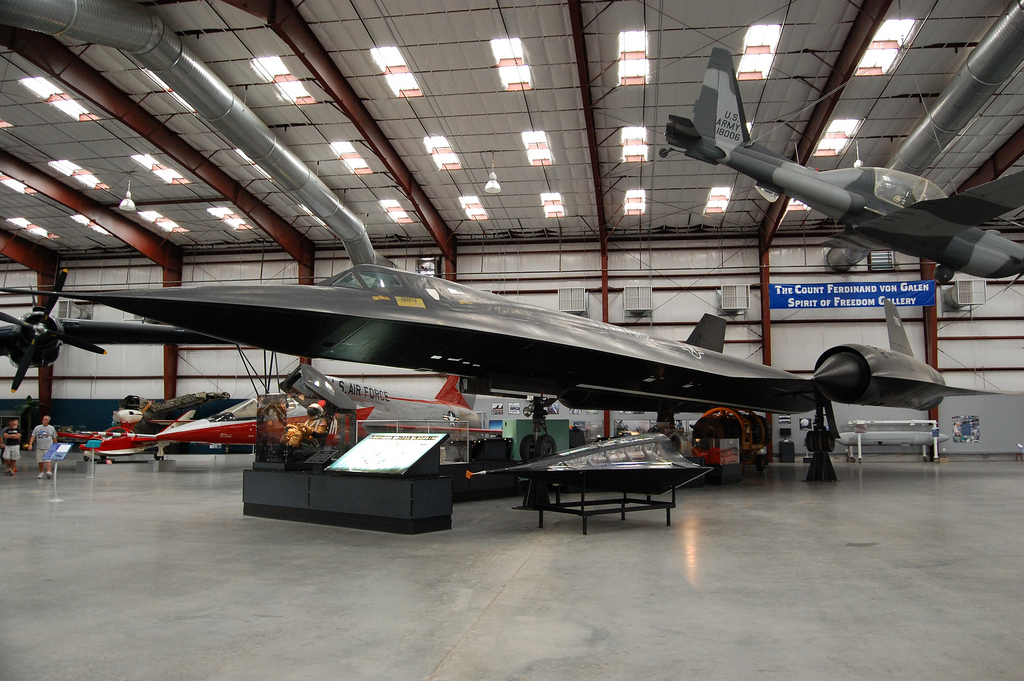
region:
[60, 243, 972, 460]
shiny black fighter jet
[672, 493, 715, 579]
light's reflection on floor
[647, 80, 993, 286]
small plane in ceiling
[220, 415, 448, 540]
small island in middle of floor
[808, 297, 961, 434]
futuristic wing on end of jet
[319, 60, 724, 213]
lights in the ceiling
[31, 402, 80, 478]
man walking in the space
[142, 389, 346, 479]
red and white color on the plane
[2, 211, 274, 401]
tip of the plane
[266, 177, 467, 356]
front window on plane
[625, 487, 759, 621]
light hitting the ground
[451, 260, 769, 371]
top of the plane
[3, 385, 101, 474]
people in the distance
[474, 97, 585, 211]
light on the roof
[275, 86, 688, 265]
many lights on roof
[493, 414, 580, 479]
tire of the plane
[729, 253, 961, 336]
blue and white sign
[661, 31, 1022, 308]
an old plane hanging from the ceiling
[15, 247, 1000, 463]
a state of the art Lockheed plane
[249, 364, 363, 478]
a replica of a pilot of a fighter jet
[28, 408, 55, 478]
a man wearing a grey shirt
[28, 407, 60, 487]
a man walking while looking upwards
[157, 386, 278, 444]
the nose of a red jet plane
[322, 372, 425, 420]
US air force decal on a plane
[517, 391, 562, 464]
a set of wheels of a plane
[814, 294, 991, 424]
the engine of a lockheed plane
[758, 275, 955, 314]
a blue banner hanging from the wall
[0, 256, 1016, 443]
Plane on display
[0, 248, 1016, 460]
Plane is on display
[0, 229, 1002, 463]
Jet on display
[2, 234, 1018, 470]
Jet is on display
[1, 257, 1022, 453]
Fighter jet on display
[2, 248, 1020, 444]
Fighter jet is on display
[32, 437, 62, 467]
Man is wearing shorts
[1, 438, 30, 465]
Person is wearing shorts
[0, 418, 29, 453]
Person is wearing a black shirt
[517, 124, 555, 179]
A light in a warehouse.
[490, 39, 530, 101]
A light in a warehouse.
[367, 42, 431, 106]
A light in a warehouse.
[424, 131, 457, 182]
A light in a warehouse.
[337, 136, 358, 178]
A light in a warehouse.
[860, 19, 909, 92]
A light in a warehouse.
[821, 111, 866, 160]
A light in a warehouse.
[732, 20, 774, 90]
A light in a warehouse.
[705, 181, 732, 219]
A light in a warehouse.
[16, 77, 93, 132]
A light in a warehouse.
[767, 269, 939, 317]
blue and white sign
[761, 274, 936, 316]
sign on the wall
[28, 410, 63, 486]
man with a grey tee shirt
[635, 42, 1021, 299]
grey plane hanging from the ceiling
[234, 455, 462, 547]
grey and black counter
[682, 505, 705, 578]
orange glare on the floor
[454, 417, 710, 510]
small black aircraft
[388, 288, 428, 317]
yellow sticker on a plane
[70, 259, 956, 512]
Plane in the hangar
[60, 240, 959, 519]
Black plane in the hangar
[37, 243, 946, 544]
Airplane in the hangar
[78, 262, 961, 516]
Black airplane in the hangar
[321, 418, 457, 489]
Plaque in front of plane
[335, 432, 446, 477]
Plaque in front of airplane